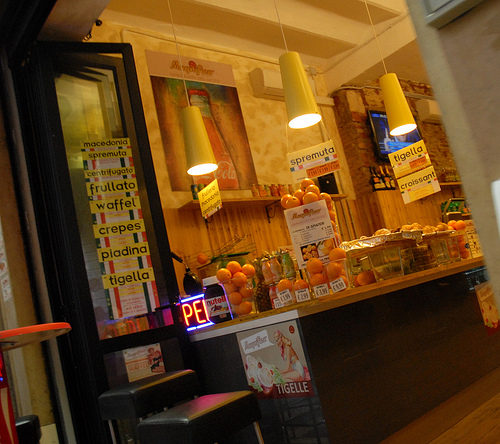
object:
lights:
[276, 7, 320, 130]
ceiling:
[105, 3, 401, 62]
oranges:
[217, 260, 255, 324]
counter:
[189, 257, 489, 342]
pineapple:
[253, 257, 274, 312]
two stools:
[96, 367, 271, 441]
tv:
[368, 108, 426, 160]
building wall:
[337, 86, 456, 180]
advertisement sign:
[235, 317, 314, 398]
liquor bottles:
[368, 163, 402, 191]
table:
[1, 320, 73, 441]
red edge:
[2, 322, 74, 342]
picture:
[145, 51, 262, 193]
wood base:
[191, 319, 497, 438]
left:
[0, 0, 156, 444]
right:
[393, 0, 500, 444]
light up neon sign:
[177, 293, 218, 332]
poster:
[285, 203, 344, 264]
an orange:
[355, 271, 372, 285]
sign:
[389, 137, 443, 206]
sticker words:
[84, 137, 158, 317]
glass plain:
[49, 50, 180, 340]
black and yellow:
[92, 197, 142, 211]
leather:
[169, 404, 202, 420]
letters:
[184, 301, 208, 323]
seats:
[103, 371, 249, 429]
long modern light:
[163, 1, 220, 177]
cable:
[160, 1, 195, 103]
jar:
[202, 273, 232, 324]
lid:
[203, 274, 220, 289]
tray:
[344, 228, 424, 248]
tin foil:
[398, 228, 421, 246]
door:
[33, 39, 186, 397]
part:
[355, 270, 402, 296]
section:
[445, 415, 472, 439]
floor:
[419, 387, 498, 442]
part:
[477, 303, 495, 326]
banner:
[475, 284, 500, 337]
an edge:
[4, 396, 21, 432]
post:
[1, 348, 23, 441]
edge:
[127, 390, 153, 441]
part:
[75, 64, 119, 123]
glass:
[65, 68, 107, 127]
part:
[181, 294, 193, 308]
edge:
[35, 321, 69, 338]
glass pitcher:
[222, 275, 255, 317]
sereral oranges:
[275, 248, 345, 300]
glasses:
[280, 257, 347, 301]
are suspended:
[165, 1, 389, 48]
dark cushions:
[98, 368, 267, 442]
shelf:
[365, 187, 437, 204]